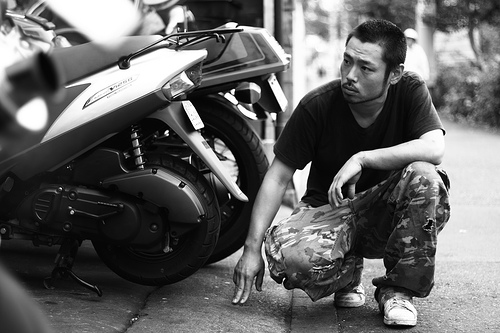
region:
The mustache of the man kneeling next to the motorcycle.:
[339, 77, 361, 88]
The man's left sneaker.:
[327, 270, 367, 302]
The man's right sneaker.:
[378, 287, 417, 322]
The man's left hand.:
[230, 252, 268, 311]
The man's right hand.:
[329, 149, 361, 204]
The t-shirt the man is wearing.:
[277, 71, 444, 192]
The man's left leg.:
[280, 195, 355, 301]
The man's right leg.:
[382, 162, 438, 295]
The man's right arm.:
[362, 126, 447, 173]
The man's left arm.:
[247, 151, 290, 248]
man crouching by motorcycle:
[29, 33, 428, 325]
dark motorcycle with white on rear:
[25, 41, 217, 331]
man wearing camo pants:
[272, 166, 499, 300]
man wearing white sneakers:
[317, 242, 442, 329]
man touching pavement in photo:
[183, 22, 339, 328]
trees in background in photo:
[283, 1, 498, 144]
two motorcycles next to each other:
[25, 26, 337, 244]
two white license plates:
[146, 76, 314, 151]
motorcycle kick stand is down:
[36, 198, 144, 315]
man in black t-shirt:
[317, 18, 452, 199]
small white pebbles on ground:
[155, 285, 222, 307]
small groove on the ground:
[69, 296, 161, 324]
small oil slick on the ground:
[33, 292, 66, 314]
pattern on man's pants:
[291, 226, 371, 253]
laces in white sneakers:
[366, 288, 436, 315]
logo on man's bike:
[75, 75, 168, 97]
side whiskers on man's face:
[368, 49, 401, 111]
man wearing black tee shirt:
[275, 96, 476, 195]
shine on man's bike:
[16, 88, 130, 139]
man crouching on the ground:
[253, 14, 454, 310]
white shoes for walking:
[352, 286, 465, 331]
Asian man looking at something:
[322, 24, 432, 120]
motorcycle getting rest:
[0, 26, 239, 238]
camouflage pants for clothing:
[296, 205, 471, 303]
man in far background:
[377, 16, 475, 137]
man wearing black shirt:
[289, 77, 471, 217]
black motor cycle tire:
[198, 100, 285, 277]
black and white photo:
[0, 7, 481, 327]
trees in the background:
[421, 9, 498, 114]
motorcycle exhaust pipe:
[4, 27, 76, 169]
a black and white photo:
[19, 22, 476, 301]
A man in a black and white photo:
[102, 20, 457, 325]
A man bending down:
[291, 13, 451, 330]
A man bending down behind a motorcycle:
[88, 19, 460, 300]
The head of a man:
[302, 16, 422, 105]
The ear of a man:
[381, 53, 417, 110]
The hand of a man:
[190, 179, 287, 321]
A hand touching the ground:
[199, 225, 278, 329]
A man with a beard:
[299, 24, 423, 125]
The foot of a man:
[350, 247, 446, 325]